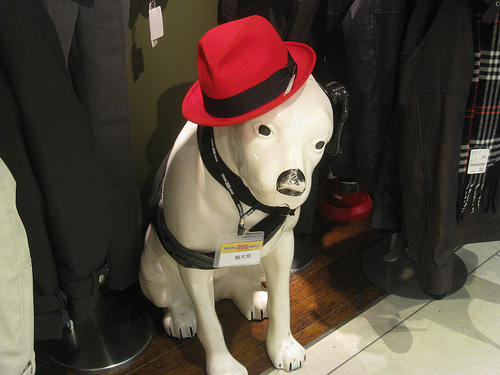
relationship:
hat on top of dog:
[181, 14, 317, 129] [137, 75, 335, 369]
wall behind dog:
[126, 5, 220, 226] [137, 75, 335, 369]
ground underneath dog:
[30, 217, 495, 370] [137, 75, 335, 369]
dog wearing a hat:
[137, 75, 335, 369] [181, 14, 317, 129]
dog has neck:
[137, 75, 335, 369] [194, 123, 306, 216]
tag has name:
[213, 232, 265, 269] [231, 250, 257, 261]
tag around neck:
[213, 232, 265, 269] [194, 123, 306, 216]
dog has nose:
[137, 75, 335, 369] [276, 168, 309, 195]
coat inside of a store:
[6, 5, 115, 340] [7, 12, 493, 370]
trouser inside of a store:
[67, 5, 143, 291] [7, 12, 493, 370]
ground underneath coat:
[30, 217, 495, 370] [6, 5, 115, 340]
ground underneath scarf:
[30, 217, 495, 370] [456, 9, 496, 224]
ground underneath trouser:
[30, 217, 495, 370] [67, 5, 143, 291]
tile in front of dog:
[273, 241, 495, 369] [137, 75, 335, 369]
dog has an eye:
[137, 75, 335, 369] [254, 121, 274, 140]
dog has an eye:
[137, 75, 335, 369] [312, 136, 327, 153]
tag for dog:
[213, 232, 265, 269] [137, 75, 335, 369]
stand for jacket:
[359, 230, 470, 299] [394, 4, 476, 298]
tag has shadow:
[213, 232, 265, 269] [183, 209, 223, 253]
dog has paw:
[137, 75, 335, 369] [264, 333, 308, 371]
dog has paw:
[137, 75, 335, 369] [205, 356, 246, 372]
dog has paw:
[137, 75, 335, 369] [162, 305, 198, 339]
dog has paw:
[137, 75, 335, 369] [236, 286, 272, 321]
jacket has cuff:
[394, 4, 476, 298] [412, 255, 457, 297]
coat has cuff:
[6, 5, 115, 340] [67, 260, 109, 320]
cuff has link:
[67, 260, 109, 320] [92, 264, 111, 293]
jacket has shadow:
[394, 4, 476, 298] [336, 250, 496, 352]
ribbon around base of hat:
[205, 52, 300, 120] [181, 14, 317, 129]